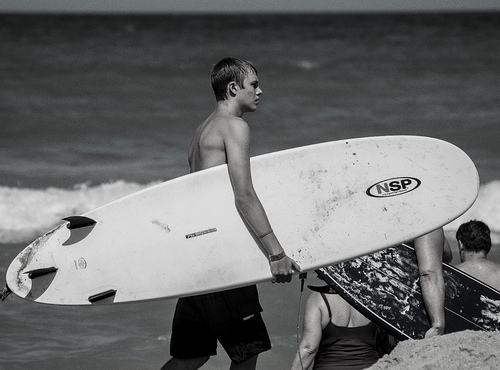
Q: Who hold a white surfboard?
A: A man.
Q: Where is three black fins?
A: On back the surfboard.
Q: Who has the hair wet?
A: A man.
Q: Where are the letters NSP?
A: On a surfboard.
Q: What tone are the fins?
A: Color black.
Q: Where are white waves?
A: In the ocean.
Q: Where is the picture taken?
A: The beach.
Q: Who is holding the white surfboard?
A: A boy.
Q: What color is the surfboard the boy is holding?
A: White.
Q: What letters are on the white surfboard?
A: NSP.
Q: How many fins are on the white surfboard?
A: Three.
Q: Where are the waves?
A: The water.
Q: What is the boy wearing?
A: Shorts.